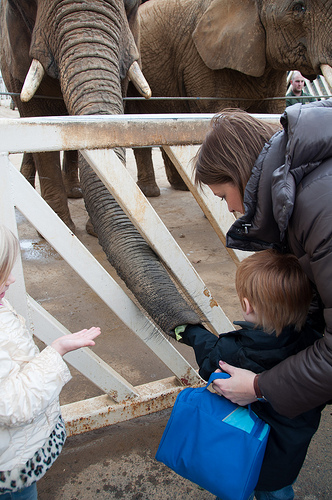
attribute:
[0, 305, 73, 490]
coat — Leopard print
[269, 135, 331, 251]
coat — Leopard print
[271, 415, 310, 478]
coat — Leopard print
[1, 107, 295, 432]
fence — dirty, white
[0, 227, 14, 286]
hair — blonde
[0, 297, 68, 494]
coat — white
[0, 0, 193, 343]
large elephant — brown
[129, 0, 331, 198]
large elephant — brown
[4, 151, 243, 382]
poles — metal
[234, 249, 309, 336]
hair — red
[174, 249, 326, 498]
boy — young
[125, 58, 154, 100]
elephant tusk — small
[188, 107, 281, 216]
hair — brown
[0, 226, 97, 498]
girl — young, blonde haired 